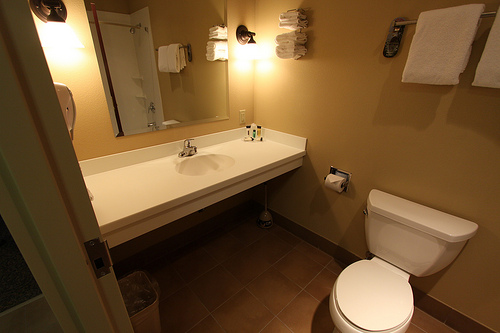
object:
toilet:
[328, 187, 479, 332]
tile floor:
[176, 225, 300, 332]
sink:
[175, 151, 234, 175]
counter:
[79, 121, 308, 248]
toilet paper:
[324, 173, 346, 193]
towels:
[274, 45, 307, 59]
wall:
[360, 97, 497, 183]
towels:
[399, 4, 486, 88]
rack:
[392, 9, 497, 28]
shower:
[94, 3, 167, 139]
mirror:
[84, 1, 230, 137]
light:
[236, 24, 259, 59]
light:
[30, 0, 86, 68]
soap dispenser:
[53, 81, 77, 143]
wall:
[2, 0, 136, 333]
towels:
[157, 42, 185, 73]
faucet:
[177, 138, 198, 158]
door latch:
[82, 233, 113, 279]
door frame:
[1, 0, 137, 332]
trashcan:
[118, 266, 162, 331]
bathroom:
[0, 0, 499, 332]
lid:
[337, 258, 414, 333]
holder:
[323, 165, 352, 193]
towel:
[471, 6, 499, 90]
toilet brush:
[257, 180, 274, 229]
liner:
[116, 269, 150, 309]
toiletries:
[257, 125, 262, 137]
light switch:
[239, 109, 245, 125]